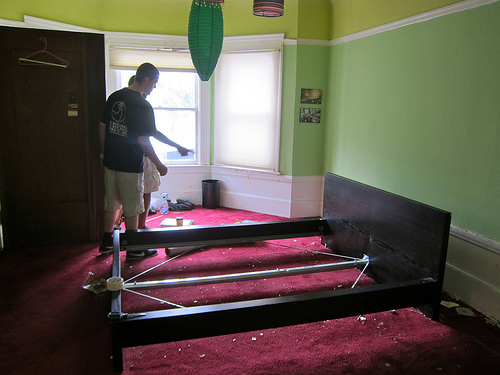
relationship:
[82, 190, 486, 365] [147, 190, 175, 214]
cleaner on floor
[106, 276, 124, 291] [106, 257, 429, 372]
tape on bed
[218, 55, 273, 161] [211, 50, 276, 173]
blind down on window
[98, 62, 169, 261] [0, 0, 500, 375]
man standing in house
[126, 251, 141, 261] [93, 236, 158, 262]
logo on shoes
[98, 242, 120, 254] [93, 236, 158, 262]
logo 2 on shoes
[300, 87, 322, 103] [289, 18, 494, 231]
picture hung on wall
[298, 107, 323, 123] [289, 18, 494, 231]
picture hung on wall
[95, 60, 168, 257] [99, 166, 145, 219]
man in shorts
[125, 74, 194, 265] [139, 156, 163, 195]
man in shorts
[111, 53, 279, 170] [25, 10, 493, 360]
bay window in house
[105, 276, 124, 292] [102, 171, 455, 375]
tape on bed